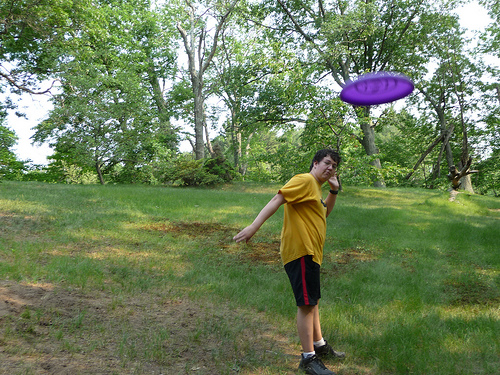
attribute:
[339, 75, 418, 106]
frisbee — purple, in motion, tossed, bright purple, in flight, blurry, in air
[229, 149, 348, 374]
boy — playing, posing, facing right, outdoors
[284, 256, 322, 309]
shorts — black in color, outdoors, black, red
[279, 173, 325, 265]
shirt — t-shirt, baggy, yellow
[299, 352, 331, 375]
shoe — black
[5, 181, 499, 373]
ground — grassy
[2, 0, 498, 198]
trees — in background, green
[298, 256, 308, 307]
stripe — deep red, red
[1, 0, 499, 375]
scene — outdoors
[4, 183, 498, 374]
grass — green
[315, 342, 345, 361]
shoe — black, grey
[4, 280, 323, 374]
grass spot — dead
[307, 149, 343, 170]
hair — straight, brown